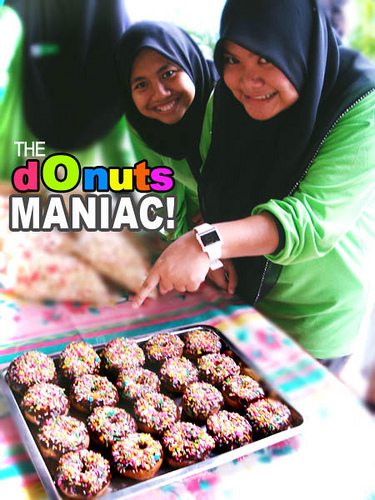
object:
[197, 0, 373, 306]
hijab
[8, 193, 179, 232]
text print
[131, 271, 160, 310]
finger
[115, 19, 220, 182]
headdress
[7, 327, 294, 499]
chocolate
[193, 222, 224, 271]
watch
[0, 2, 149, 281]
person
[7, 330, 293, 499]
donut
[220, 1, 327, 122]
head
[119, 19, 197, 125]
head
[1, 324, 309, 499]
pan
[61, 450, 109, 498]
sprinkles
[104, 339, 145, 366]
sprinkles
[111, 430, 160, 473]
sprinkles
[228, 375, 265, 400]
sprinkles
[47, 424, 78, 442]
sprinkles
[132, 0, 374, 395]
woman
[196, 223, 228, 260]
wrist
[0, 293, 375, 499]
tablecloth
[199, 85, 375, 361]
top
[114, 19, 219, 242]
person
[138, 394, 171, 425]
sprinkles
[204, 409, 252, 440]
sprinkles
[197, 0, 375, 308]
burkas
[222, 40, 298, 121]
face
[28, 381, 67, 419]
sprinkles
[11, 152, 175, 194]
text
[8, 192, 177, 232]
maniac!